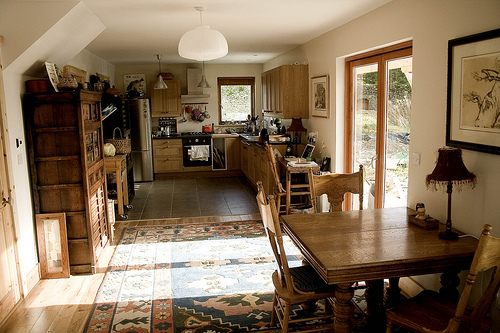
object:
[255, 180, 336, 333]
chair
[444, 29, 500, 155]
painting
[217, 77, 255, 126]
kitchen window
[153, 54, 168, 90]
silver light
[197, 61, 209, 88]
silver light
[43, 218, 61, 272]
mirror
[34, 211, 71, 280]
frame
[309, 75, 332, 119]
frame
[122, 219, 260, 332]
carpet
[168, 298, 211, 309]
blue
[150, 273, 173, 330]
red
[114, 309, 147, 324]
white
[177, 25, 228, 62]
light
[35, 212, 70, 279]
picture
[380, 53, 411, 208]
glass door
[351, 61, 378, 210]
glass door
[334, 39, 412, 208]
door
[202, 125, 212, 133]
pot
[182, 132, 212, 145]
stove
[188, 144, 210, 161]
towel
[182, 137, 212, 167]
door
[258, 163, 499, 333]
table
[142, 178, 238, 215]
tile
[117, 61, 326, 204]
kitchen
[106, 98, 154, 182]
refrigerator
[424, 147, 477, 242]
lamp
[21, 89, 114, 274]
cabinet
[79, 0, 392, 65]
ceiling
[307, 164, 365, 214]
chair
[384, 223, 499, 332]
chair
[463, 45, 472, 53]
matting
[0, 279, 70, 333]
floor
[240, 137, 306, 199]
counter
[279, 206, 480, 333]
dining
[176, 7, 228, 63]
fixtures